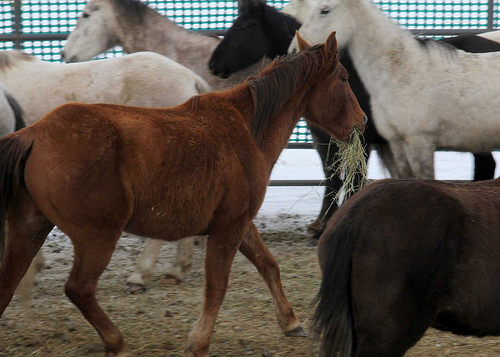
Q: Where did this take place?
A: A corral.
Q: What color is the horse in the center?
A: Brown.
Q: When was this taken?
A: Daytime.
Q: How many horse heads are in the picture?
A: Four.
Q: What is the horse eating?
A: Hay.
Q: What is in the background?
A: Fence.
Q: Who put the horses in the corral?
A: No indication of who.